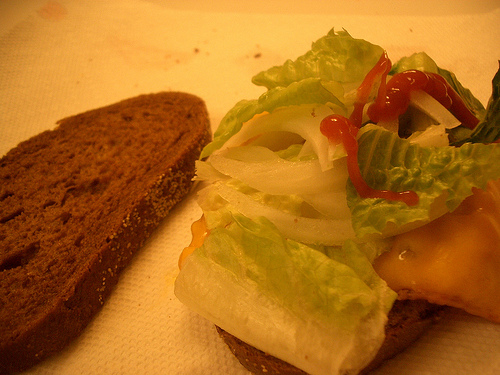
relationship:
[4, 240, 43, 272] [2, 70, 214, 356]
hole in bread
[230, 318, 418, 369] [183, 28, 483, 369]
bread under lettuce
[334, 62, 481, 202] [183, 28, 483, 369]
ketchup on lettuce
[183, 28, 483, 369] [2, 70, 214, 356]
lettuce next to bread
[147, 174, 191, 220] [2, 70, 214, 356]
seeds on bread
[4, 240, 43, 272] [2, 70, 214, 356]
hole on bread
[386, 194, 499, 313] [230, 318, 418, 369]
cheese over bread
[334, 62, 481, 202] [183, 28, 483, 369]
ketchup over lettuce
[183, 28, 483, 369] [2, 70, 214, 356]
lettuce on bread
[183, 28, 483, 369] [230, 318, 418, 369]
lettuce on bread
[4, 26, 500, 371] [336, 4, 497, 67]
sandwich on napkin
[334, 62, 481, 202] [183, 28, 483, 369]
ketchup and lettuce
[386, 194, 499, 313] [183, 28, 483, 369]
cheese under lettuce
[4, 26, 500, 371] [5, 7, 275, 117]
sandwich on saviat